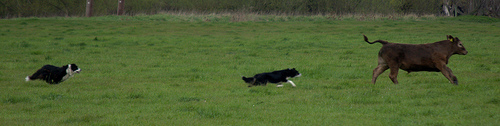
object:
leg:
[387, 60, 399, 85]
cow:
[361, 35, 468, 86]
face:
[71, 63, 83, 73]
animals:
[240, 68, 302, 87]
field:
[0, 13, 499, 125]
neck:
[434, 40, 457, 55]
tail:
[360, 33, 386, 44]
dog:
[23, 63, 84, 85]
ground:
[2, 15, 499, 126]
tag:
[447, 39, 453, 41]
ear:
[444, 35, 456, 39]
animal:
[361, 34, 467, 85]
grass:
[0, 16, 500, 126]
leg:
[371, 65, 387, 84]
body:
[368, 42, 462, 86]